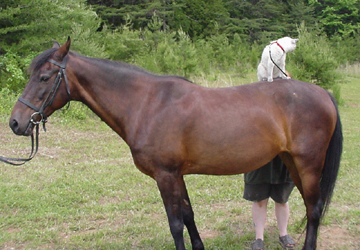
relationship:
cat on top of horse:
[256, 35, 297, 85] [8, 35, 344, 249]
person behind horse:
[244, 155, 296, 249] [8, 35, 344, 249]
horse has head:
[8, 35, 344, 249] [9, 34, 71, 137]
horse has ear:
[8, 35, 344, 249] [52, 36, 73, 62]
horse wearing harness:
[8, 35, 344, 249] [0, 57, 69, 167]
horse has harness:
[8, 35, 344, 249] [0, 57, 69, 167]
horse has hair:
[8, 35, 344, 249] [29, 45, 59, 74]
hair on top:
[29, 45, 59, 74] [26, 34, 109, 80]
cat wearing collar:
[256, 35, 297, 85] [275, 40, 286, 56]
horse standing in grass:
[8, 35, 344, 249] [1, 62, 358, 249]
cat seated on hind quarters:
[256, 35, 297, 85] [252, 78, 318, 109]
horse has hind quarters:
[8, 35, 344, 249] [252, 78, 318, 109]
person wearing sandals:
[244, 155, 296, 249] [276, 234, 296, 249]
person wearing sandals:
[244, 155, 296, 249] [250, 238, 265, 249]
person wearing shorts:
[244, 155, 296, 249] [244, 153, 296, 204]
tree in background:
[0, 2, 109, 104] [2, 1, 358, 124]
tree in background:
[92, 2, 166, 31] [2, 1, 358, 124]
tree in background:
[170, 2, 233, 43] [2, 1, 358, 124]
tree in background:
[315, 1, 359, 39] [2, 1, 358, 124]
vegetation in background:
[2, 11, 357, 105] [2, 1, 358, 124]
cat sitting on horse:
[256, 35, 297, 85] [8, 35, 344, 249]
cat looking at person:
[256, 35, 297, 85] [244, 155, 296, 249]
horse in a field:
[8, 35, 344, 249] [4, 39, 357, 249]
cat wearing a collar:
[256, 35, 297, 85] [275, 40, 286, 56]